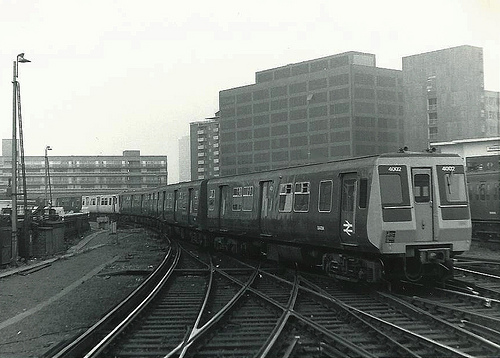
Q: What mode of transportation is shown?
A: Train.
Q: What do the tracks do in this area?
A: Cross.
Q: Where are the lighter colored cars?
A: Towards the back.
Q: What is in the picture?
A: A train.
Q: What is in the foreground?
A: Train tracks.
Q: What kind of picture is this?
A: Black and white.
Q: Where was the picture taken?
A: In the city.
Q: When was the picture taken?
A: During the daytime.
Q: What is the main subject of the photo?
A: A train.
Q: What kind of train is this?
A: Passenger train.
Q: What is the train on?
A: Tracks.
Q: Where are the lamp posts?
A: On the left.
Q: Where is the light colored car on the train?
A: At the end.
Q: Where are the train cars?
A: On the tracks.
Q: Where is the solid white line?
A: The right of the train.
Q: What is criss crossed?
A: The train tracks.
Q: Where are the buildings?
A: Behind the train.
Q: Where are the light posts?
A: The right of the train.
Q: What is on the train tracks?
A: A train.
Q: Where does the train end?
A: Around the turn.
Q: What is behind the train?
A: Buildings.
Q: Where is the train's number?
A: On the front.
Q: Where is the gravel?
A: Between the tracks.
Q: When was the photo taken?
A: Daytime.